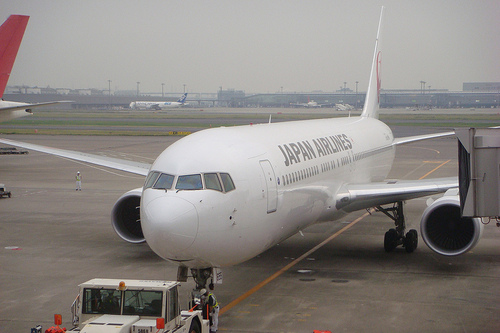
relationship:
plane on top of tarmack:
[2, 3, 481, 257] [1, 131, 500, 332]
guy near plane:
[201, 288, 221, 332] [2, 3, 481, 257]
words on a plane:
[278, 133, 353, 167] [2, 3, 481, 257]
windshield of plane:
[143, 169, 237, 194] [2, 3, 481, 257]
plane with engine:
[2, 3, 481, 257] [421, 196, 480, 257]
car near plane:
[36, 278, 212, 332] [2, 3, 481, 257]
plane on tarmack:
[2, 3, 481, 257] [1, 131, 500, 332]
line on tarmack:
[216, 157, 453, 316] [1, 131, 500, 332]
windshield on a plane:
[143, 169, 237, 194] [2, 3, 481, 257]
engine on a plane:
[421, 196, 480, 257] [2, 3, 481, 257]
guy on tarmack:
[201, 288, 221, 332] [1, 131, 500, 332]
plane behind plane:
[130, 93, 189, 111] [2, 3, 481, 257]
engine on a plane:
[109, 183, 146, 243] [2, 3, 481, 257]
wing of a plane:
[1, 138, 152, 174] [2, 3, 481, 257]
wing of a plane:
[337, 178, 462, 210] [2, 3, 481, 257]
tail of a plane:
[1, 14, 31, 104] [2, 3, 481, 257]